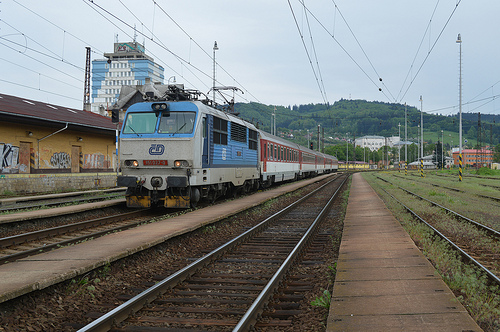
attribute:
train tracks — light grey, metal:
[82, 175, 346, 329]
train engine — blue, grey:
[109, 93, 263, 198]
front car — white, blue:
[116, 97, 261, 193]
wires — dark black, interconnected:
[276, 17, 467, 121]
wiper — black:
[171, 122, 187, 136]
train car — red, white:
[261, 136, 303, 179]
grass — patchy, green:
[410, 185, 480, 236]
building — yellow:
[1, 112, 118, 172]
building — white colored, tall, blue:
[82, 29, 172, 96]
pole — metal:
[83, 47, 92, 104]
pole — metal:
[456, 42, 463, 149]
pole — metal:
[418, 100, 425, 157]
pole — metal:
[396, 125, 403, 161]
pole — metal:
[210, 49, 216, 103]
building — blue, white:
[88, 34, 166, 117]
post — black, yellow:
[454, 31, 466, 192]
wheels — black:
[190, 175, 276, 203]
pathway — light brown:
[326, 170, 473, 330]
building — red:
[444, 145, 491, 167]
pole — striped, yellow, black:
[455, 150, 466, 180]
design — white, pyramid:
[96, 58, 139, 117]